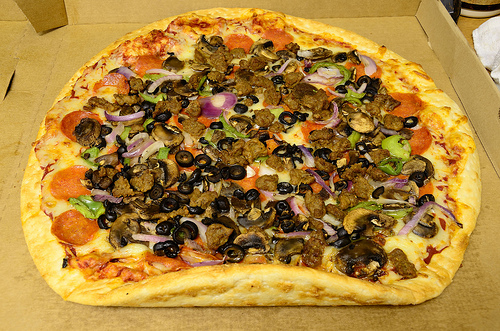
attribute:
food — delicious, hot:
[21, 7, 483, 311]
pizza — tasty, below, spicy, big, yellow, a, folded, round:
[22, 7, 483, 306]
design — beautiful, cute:
[89, 74, 422, 258]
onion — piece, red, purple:
[101, 107, 146, 125]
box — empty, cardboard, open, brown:
[0, 1, 499, 329]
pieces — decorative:
[207, 25, 378, 111]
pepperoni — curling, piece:
[53, 208, 99, 246]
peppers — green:
[376, 158, 405, 177]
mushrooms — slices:
[106, 213, 142, 248]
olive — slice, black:
[176, 148, 193, 167]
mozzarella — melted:
[38, 130, 70, 165]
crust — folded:
[114, 260, 372, 309]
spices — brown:
[166, 19, 228, 49]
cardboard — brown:
[4, 4, 65, 94]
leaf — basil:
[348, 200, 416, 216]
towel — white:
[472, 12, 499, 84]